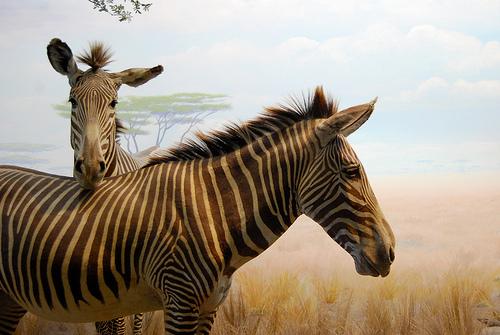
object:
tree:
[52, 92, 232, 155]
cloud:
[0, 0, 500, 173]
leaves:
[89, 0, 152, 25]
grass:
[290, 286, 355, 333]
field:
[0, 184, 500, 335]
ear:
[115, 64, 164, 89]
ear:
[45, 38, 78, 82]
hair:
[140, 84, 340, 168]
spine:
[173, 118, 323, 171]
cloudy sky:
[0, 0, 500, 169]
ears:
[319, 96, 381, 139]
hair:
[73, 39, 116, 72]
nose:
[72, 159, 107, 176]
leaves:
[155, 102, 205, 118]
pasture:
[0, 173, 500, 335]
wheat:
[218, 261, 497, 335]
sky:
[1, 0, 500, 170]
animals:
[0, 37, 396, 335]